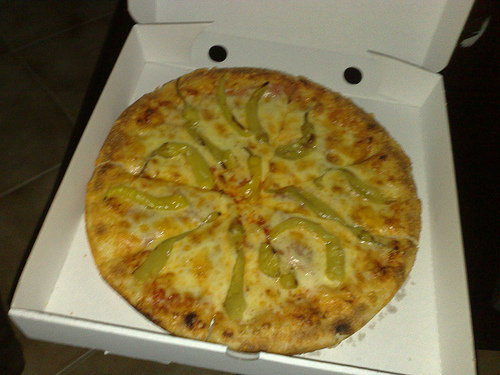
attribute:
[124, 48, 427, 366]
pie — PIZZA, ROUND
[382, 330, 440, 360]
box — CARDBOARD, WHITE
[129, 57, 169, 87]
box — PIZZA, OPEN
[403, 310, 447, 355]
box — PIZZA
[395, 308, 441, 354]
box — PIZZA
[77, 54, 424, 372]
pizza — baked, TOP, CHEESE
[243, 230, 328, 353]
slice — PIZZA, TRIANGULAR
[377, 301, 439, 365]
box — PIZZA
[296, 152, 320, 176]
cheese — WHITE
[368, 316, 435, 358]
box — WHITE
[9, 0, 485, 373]
box — white, cardboard, pizza, big